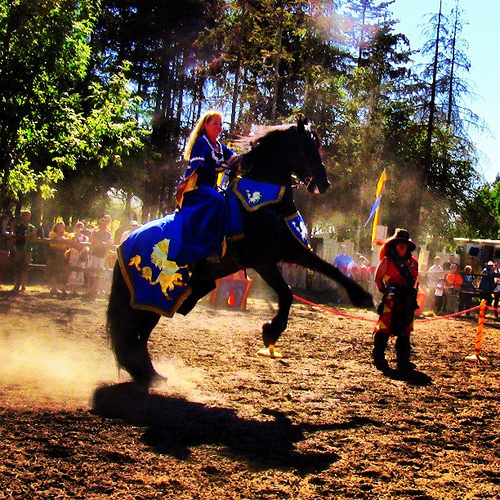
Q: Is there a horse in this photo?
A: Yes, there is a horse.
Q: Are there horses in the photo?
A: Yes, there is a horse.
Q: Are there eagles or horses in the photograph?
A: Yes, there is a horse.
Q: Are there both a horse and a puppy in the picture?
A: No, there is a horse but no puppies.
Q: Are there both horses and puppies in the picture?
A: No, there is a horse but no puppies.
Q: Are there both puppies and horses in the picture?
A: No, there is a horse but no puppies.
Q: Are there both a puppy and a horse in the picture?
A: No, there is a horse but no puppies.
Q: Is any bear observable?
A: No, there are no bears.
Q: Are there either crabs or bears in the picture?
A: No, there are no bears or crabs.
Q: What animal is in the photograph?
A: The animal is a horse.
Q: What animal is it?
A: The animal is a horse.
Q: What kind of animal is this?
A: This is a horse.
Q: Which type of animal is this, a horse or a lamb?
A: This is a horse.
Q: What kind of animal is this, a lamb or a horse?
A: This is a horse.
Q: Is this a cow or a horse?
A: This is a horse.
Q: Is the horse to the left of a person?
A: Yes, the horse is to the left of a person.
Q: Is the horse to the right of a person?
A: No, the horse is to the left of a person.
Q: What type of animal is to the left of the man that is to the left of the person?
A: The animal is a horse.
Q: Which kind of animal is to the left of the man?
A: The animal is a horse.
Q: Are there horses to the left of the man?
A: Yes, there is a horse to the left of the man.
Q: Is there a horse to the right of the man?
A: No, the horse is to the left of the man.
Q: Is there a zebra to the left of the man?
A: No, there is a horse to the left of the man.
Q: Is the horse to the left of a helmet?
A: No, the horse is to the left of the man.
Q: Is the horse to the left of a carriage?
A: No, the horse is to the left of a person.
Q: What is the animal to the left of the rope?
A: The animal is a horse.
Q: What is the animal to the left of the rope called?
A: The animal is a horse.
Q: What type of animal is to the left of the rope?
A: The animal is a horse.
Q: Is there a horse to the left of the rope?
A: Yes, there is a horse to the left of the rope.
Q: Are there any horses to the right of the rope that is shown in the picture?
A: No, the horse is to the left of the rope.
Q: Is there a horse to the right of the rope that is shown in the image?
A: No, the horse is to the left of the rope.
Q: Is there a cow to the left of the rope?
A: No, there is a horse to the left of the rope.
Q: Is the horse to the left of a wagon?
A: No, the horse is to the left of a rope.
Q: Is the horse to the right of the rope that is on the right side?
A: No, the horse is to the left of the rope.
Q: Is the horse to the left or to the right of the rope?
A: The horse is to the left of the rope.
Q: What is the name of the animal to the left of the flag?
A: The animal is a horse.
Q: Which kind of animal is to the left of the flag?
A: The animal is a horse.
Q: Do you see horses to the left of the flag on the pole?
A: Yes, there is a horse to the left of the flag.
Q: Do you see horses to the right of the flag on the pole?
A: No, the horse is to the left of the flag.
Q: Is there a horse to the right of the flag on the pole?
A: No, the horse is to the left of the flag.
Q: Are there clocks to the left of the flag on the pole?
A: No, there is a horse to the left of the flag.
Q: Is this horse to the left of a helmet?
A: No, the horse is to the left of the flag.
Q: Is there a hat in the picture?
A: Yes, there is a hat.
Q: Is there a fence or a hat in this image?
A: Yes, there is a hat.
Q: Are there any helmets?
A: No, there are no helmets.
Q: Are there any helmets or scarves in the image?
A: No, there are no helmets or scarves.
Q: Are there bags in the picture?
A: No, there are no bags.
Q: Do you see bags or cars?
A: No, there are no bags or cars.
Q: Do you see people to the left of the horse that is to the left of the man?
A: Yes, there is a person to the left of the horse.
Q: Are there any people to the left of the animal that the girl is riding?
A: Yes, there is a person to the left of the horse.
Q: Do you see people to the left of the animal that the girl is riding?
A: Yes, there is a person to the left of the horse.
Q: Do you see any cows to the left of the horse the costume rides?
A: No, there is a person to the left of the horse.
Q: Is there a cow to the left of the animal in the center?
A: No, there is a person to the left of the horse.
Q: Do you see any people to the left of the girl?
A: Yes, there is a person to the left of the girl.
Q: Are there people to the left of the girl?
A: Yes, there is a person to the left of the girl.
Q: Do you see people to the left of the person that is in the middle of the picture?
A: Yes, there is a person to the left of the girl.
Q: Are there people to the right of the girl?
A: No, the person is to the left of the girl.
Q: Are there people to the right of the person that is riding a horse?
A: No, the person is to the left of the girl.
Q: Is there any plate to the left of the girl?
A: No, there is a person to the left of the girl.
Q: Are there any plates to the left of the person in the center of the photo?
A: No, there is a person to the left of the girl.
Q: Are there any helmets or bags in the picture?
A: No, there are no helmets or bags.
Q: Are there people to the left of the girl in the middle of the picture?
A: Yes, there is a person to the left of the girl.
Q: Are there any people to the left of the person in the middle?
A: Yes, there is a person to the left of the girl.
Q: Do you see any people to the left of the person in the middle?
A: Yes, there is a person to the left of the girl.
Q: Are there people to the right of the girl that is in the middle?
A: No, the person is to the left of the girl.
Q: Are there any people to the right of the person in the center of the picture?
A: No, the person is to the left of the girl.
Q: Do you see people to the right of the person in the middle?
A: No, the person is to the left of the girl.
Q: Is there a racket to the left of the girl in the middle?
A: No, there is a person to the left of the girl.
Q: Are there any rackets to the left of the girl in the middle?
A: No, there is a person to the left of the girl.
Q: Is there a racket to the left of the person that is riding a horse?
A: No, there is a person to the left of the girl.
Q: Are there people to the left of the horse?
A: Yes, there is a person to the left of the horse.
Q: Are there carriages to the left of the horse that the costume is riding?
A: No, there is a person to the left of the horse.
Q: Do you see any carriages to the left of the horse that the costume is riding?
A: No, there is a person to the left of the horse.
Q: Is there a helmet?
A: No, there are no helmets.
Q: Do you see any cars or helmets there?
A: No, there are no helmets or cars.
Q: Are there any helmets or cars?
A: No, there are no helmets or cars.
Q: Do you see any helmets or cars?
A: No, there are no helmets or cars.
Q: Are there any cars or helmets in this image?
A: No, there are no helmets or cars.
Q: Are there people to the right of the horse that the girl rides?
A: Yes, there is a person to the right of the horse.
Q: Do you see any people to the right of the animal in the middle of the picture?
A: Yes, there is a person to the right of the horse.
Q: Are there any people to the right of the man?
A: Yes, there is a person to the right of the man.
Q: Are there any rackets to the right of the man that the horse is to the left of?
A: No, there is a person to the right of the man.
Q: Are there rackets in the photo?
A: No, there are no rackets.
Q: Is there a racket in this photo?
A: No, there are no rackets.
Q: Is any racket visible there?
A: No, there are no rackets.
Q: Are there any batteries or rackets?
A: No, there are no rackets or batteries.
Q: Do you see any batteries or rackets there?
A: No, there are no rackets or batteries.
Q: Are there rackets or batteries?
A: No, there are no rackets or batteries.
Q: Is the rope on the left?
A: No, the rope is on the right of the image.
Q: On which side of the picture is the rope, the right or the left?
A: The rope is on the right of the image.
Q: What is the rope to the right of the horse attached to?
A: The rope is attached to the pole.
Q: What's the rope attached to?
A: The rope is attached to the pole.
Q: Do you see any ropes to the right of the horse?
A: Yes, there is a rope to the right of the horse.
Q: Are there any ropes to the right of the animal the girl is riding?
A: Yes, there is a rope to the right of the horse.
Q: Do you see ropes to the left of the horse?
A: No, the rope is to the right of the horse.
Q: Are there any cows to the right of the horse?
A: No, there is a rope to the right of the horse.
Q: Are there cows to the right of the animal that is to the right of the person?
A: No, there is a rope to the right of the horse.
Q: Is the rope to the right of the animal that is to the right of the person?
A: Yes, the rope is to the right of the horse.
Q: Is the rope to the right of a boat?
A: No, the rope is to the right of the horse.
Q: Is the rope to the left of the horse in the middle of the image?
A: No, the rope is to the right of the horse.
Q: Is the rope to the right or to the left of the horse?
A: The rope is to the right of the horse.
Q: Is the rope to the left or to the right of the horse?
A: The rope is to the right of the horse.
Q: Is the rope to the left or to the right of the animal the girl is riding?
A: The rope is to the right of the horse.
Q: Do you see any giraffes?
A: No, there are no giraffes.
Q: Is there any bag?
A: No, there are no bags.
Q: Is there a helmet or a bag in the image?
A: No, there are no bags or helmets.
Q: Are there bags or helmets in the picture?
A: No, there are no bags or helmets.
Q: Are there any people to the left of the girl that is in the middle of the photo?
A: Yes, there is a person to the left of the girl.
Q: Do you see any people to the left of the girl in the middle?
A: Yes, there is a person to the left of the girl.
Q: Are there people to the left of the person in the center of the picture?
A: Yes, there is a person to the left of the girl.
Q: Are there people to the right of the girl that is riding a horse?
A: No, the person is to the left of the girl.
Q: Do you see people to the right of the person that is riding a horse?
A: No, the person is to the left of the girl.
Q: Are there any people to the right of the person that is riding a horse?
A: No, the person is to the left of the girl.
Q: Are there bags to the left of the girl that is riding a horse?
A: No, there is a person to the left of the girl.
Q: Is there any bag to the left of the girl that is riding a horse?
A: No, there is a person to the left of the girl.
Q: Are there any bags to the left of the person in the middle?
A: No, there is a person to the left of the girl.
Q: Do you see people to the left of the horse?
A: Yes, there is a person to the left of the horse.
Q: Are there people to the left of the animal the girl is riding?
A: Yes, there is a person to the left of the horse.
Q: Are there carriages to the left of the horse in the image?
A: No, there is a person to the left of the horse.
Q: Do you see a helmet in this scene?
A: No, there are no helmets.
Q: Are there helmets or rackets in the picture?
A: No, there are no helmets or rackets.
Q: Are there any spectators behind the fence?
A: Yes, there are spectators behind the fence.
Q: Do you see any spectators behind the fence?
A: Yes, there are spectators behind the fence.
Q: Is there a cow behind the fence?
A: No, there are spectators behind the fence.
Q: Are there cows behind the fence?
A: No, there are spectators behind the fence.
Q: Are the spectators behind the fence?
A: Yes, the spectators are behind the fence.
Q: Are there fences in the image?
A: Yes, there is a fence.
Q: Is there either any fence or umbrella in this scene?
A: Yes, there is a fence.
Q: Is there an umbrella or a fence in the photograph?
A: Yes, there is a fence.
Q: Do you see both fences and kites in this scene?
A: No, there is a fence but no kites.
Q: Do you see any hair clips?
A: No, there are no hair clips.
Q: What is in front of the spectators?
A: The fence is in front of the spectators.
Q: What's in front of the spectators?
A: The fence is in front of the spectators.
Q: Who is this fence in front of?
A: The fence is in front of the spectators.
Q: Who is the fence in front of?
A: The fence is in front of the spectators.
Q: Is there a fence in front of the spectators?
A: Yes, there is a fence in front of the spectators.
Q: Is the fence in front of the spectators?
A: Yes, the fence is in front of the spectators.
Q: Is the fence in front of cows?
A: No, the fence is in front of the spectators.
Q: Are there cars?
A: No, there are no cars.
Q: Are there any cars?
A: No, there are no cars.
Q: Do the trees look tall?
A: Yes, the trees are tall.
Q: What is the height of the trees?
A: The trees are tall.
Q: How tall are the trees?
A: The trees are tall.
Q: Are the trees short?
A: No, the trees are tall.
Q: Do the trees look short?
A: No, the trees are tall.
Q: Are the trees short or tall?
A: The trees are tall.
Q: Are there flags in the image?
A: Yes, there is a flag.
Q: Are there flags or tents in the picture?
A: Yes, there is a flag.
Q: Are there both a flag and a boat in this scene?
A: No, there is a flag but no boats.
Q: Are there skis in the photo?
A: No, there are no skis.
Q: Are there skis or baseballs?
A: No, there are no skis or baseballs.